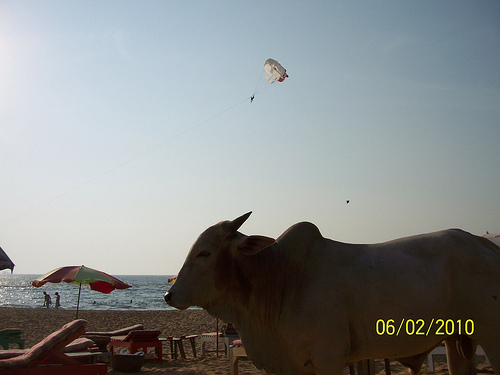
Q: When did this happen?
A: June second 2010.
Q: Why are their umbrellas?
A: Because it is sunny out.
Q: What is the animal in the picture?
A: A male cow.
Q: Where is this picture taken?
A: A beach.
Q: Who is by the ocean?
A: Two kids.